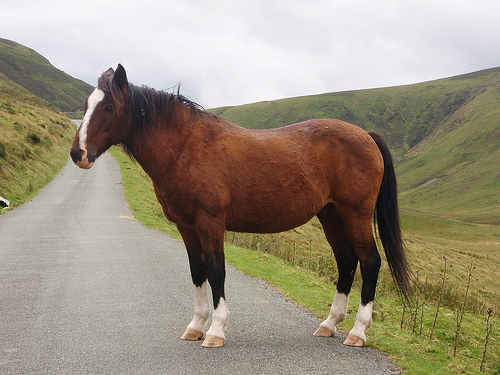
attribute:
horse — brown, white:
[80, 65, 392, 345]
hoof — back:
[315, 329, 333, 337]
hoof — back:
[343, 335, 364, 353]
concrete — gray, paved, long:
[6, 116, 395, 375]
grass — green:
[110, 66, 494, 375]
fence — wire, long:
[238, 225, 499, 373]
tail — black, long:
[368, 131, 417, 311]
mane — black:
[111, 70, 207, 145]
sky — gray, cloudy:
[2, 3, 499, 96]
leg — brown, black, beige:
[193, 210, 231, 349]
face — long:
[70, 72, 123, 162]